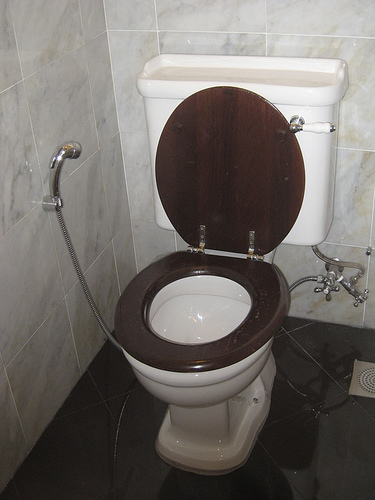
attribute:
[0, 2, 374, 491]
wall — beige, marble, tiled, white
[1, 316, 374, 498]
floor — dark brown, ceramic, black, tiled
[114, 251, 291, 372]
seat — brown, scratched, dark brown, spotted, wooden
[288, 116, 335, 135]
handle — silver, white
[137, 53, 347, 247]
tank — white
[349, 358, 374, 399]
drain — white, silver, beige, metal, shiny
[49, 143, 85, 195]
spray nozzle — chrome, shiny, ridged, silver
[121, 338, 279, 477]
toilet — white, clean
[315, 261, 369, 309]
knobs — silver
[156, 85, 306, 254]
lid — dark brown, brown, wooden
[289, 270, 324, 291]
pipe — silver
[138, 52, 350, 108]
lid — white